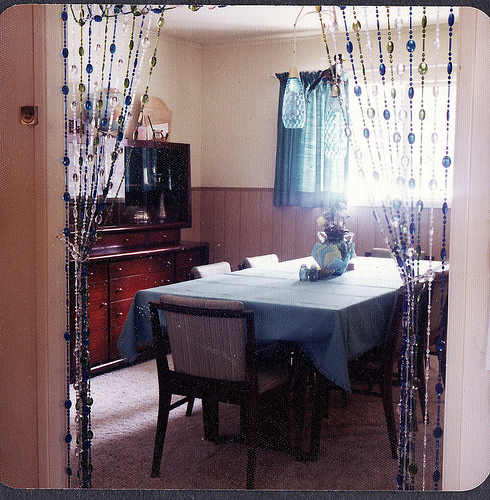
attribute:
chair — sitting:
[144, 304, 302, 482]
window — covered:
[332, 109, 428, 200]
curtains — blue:
[251, 64, 387, 189]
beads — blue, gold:
[318, 117, 476, 221]